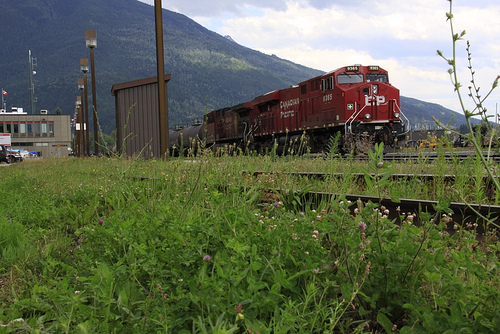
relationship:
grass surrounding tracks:
[21, 175, 259, 300] [99, 156, 491, 229]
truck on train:
[171, 107, 209, 147] [177, 57, 410, 152]